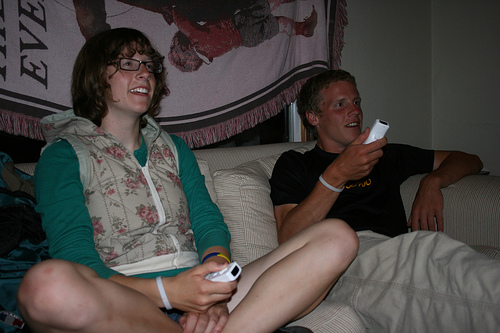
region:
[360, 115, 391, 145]
a white wii controller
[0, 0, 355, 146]
part of a large blanket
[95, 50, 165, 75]
a woman's eyeglasses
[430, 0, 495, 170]
part of a white wall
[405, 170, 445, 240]
a man's hand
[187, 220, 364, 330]
the leg of a woman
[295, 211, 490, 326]
part of a beige blanket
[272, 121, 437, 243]
a man's black shirt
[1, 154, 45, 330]
part of a decorative pillow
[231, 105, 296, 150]
part of a window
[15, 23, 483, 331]
Two people playing a game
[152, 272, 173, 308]
White band on woman's right wrist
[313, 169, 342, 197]
Man wearing white band on his right wrist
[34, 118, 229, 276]
Green and printed jacket woman is wearing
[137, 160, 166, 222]
White zipper down the front of woman's jacket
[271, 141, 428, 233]
Black top man is wearing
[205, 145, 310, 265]
White pillow in back of man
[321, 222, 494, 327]
Sheet covering man in bed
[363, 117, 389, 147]
White and black controller in man's hand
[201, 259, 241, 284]
Woman holding white and black controller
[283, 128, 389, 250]
the shirt is black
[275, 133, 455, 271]
the shirt is black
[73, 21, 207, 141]
a woman wearing eyeglasses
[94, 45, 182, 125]
a woman wearing eyeglasses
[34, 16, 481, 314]
people holding wii controllers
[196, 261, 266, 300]
controller is white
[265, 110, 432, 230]
person wearing black t shirt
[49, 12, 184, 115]
person has brown hair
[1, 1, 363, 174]
rug hanging on the wall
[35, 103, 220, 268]
girl wearing a vest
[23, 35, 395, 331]
girl who has her legs crossed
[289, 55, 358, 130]
guy has brown hair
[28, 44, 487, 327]
people sitting on the couch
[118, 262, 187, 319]
wearing a white bracelet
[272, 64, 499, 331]
a young man sitting on couch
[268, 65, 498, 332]
a young man playing video game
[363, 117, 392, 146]
a Wii video game controller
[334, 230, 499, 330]
a pair of light grey pants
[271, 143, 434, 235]
a black t-shirt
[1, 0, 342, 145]
a Norman Rockwell blanket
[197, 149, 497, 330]
a white striped couch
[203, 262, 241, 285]
a Wii video game contrller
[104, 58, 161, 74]
a pair of eyeglasses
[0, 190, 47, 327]
a shiny blue pillow